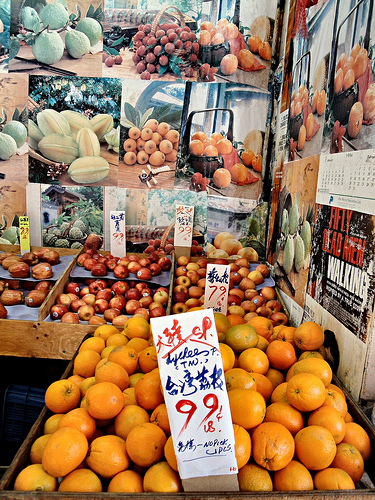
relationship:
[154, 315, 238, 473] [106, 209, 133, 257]
writing on sign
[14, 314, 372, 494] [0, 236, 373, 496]
oranges in crates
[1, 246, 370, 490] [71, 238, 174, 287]
fruit in crate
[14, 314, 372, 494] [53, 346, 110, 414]
oranges in box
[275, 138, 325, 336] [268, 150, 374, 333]
poster on wall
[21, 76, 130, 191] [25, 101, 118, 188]
poster on fruit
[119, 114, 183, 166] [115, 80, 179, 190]
fruit on poster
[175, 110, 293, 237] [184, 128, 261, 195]
picture on fruit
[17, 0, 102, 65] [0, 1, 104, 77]
green pears on pictures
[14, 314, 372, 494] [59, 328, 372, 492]
oranges in box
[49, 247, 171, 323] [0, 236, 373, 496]
apples in crates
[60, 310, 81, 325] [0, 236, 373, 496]
apple in crates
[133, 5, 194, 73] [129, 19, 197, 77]
basket in grapes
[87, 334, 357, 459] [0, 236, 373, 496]
oranges in crates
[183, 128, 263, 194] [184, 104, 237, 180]
oranges in basket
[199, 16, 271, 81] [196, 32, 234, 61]
oranges in basket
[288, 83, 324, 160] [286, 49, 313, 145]
oranges in basket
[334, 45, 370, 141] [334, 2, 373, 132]
oranges in basket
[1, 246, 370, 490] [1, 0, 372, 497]
fruit in stand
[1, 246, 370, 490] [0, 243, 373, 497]
fruit in stand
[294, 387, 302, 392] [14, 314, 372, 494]
stem on oranges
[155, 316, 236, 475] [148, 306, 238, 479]
writing on sign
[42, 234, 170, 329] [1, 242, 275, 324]
apples on blue trays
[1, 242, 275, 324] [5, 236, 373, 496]
blue trays on crates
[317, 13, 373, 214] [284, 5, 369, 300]
calendar on wall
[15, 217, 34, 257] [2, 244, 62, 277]
sign for apples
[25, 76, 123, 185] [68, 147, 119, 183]
pciture on table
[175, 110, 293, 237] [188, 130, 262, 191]
picture of oranges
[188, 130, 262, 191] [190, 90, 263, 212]
oranges in basket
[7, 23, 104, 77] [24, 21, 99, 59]
pictures of pears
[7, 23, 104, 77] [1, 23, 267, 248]
pictures on wall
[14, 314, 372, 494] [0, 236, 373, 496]
oranges in a crates